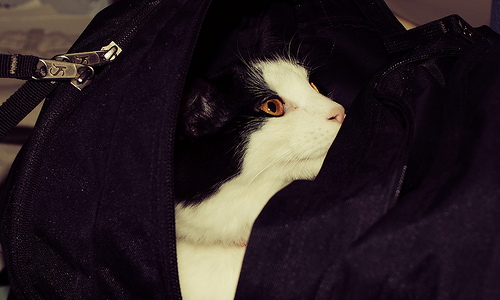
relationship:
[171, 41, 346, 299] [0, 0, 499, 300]
cat sitting in backpack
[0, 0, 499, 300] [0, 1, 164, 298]
backpack has a zipper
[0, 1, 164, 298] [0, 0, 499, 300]
zipper on backpack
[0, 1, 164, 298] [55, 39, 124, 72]
zipper has a pull tab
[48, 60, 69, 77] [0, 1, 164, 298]
logo on zipper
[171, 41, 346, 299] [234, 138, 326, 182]
cat has whiskers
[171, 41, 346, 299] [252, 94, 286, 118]
cat has an eye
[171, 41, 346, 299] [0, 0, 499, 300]
cat sitting inside a backpack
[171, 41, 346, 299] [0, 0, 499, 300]
cat hiding inside backpack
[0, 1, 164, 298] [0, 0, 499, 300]
zipper attached to backpack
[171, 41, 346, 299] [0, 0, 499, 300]
cat sitting in a backpack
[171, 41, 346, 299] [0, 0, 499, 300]
cat inside a backpack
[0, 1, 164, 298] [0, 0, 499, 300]
zipper on a backpack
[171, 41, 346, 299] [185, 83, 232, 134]
cat has an ear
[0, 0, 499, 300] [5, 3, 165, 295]
backpack has zippers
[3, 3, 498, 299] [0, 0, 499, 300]
backpack has a backpack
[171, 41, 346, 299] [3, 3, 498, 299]
cat inside backpack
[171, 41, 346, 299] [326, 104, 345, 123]
cat has a nose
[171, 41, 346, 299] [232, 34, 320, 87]
cat has eyelashes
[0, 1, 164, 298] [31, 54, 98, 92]
zipper has a tag